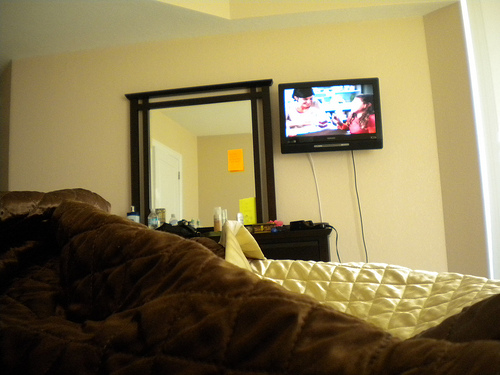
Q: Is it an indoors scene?
A: Yes, it is indoors.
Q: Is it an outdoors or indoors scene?
A: It is indoors.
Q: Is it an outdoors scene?
A: No, it is indoors.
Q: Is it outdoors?
A: No, it is indoors.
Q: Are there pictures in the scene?
A: No, there are no pictures.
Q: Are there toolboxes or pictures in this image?
A: No, there are no pictures or toolboxes.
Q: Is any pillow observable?
A: No, there are no pillows.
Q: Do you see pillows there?
A: No, there are no pillows.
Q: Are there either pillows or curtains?
A: No, there are no pillows or curtains.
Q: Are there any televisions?
A: Yes, there is a television.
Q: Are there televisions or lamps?
A: Yes, there is a television.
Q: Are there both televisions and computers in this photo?
A: No, there is a television but no computers.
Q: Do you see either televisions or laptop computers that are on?
A: Yes, the television is on.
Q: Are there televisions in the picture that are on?
A: Yes, there is a television that is on.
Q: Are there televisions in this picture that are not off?
A: Yes, there is a television that is on.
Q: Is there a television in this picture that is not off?
A: Yes, there is a television that is on.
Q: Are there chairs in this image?
A: No, there are no chairs.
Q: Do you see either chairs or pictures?
A: No, there are no chairs or pictures.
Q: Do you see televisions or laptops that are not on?
A: No, there is a television but it is on.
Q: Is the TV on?
A: Yes, the TV is on.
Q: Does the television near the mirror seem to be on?
A: Yes, the TV is on.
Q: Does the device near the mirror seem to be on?
A: Yes, the TV is on.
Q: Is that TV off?
A: No, the TV is on.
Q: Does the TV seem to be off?
A: No, the TV is on.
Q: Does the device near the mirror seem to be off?
A: No, the TV is on.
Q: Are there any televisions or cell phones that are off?
A: No, there is a television but it is on.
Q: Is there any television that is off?
A: No, there is a television but it is on.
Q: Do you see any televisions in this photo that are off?
A: No, there is a television but it is on.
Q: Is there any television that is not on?
A: No, there is a television but it is on.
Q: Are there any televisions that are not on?
A: No, there is a television but it is on.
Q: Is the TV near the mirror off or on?
A: The television is on.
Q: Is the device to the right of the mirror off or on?
A: The television is on.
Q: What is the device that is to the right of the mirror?
A: The device is a television.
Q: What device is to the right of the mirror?
A: The device is a television.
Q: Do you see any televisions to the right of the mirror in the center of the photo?
A: Yes, there is a television to the right of the mirror.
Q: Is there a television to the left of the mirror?
A: No, the television is to the right of the mirror.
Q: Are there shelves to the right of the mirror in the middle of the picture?
A: No, there is a television to the right of the mirror.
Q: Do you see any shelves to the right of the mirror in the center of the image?
A: No, there is a television to the right of the mirror.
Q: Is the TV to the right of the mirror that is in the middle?
A: Yes, the TV is to the right of the mirror.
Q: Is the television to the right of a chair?
A: No, the television is to the right of the mirror.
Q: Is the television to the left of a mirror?
A: No, the television is to the right of a mirror.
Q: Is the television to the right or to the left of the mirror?
A: The television is to the right of the mirror.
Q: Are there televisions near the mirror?
A: Yes, there is a television near the mirror.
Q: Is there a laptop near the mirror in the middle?
A: No, there is a television near the mirror.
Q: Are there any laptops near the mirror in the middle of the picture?
A: No, there is a television near the mirror.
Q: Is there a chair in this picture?
A: No, there are no chairs.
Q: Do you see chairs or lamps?
A: No, there are no chairs or lamps.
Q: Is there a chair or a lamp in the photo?
A: No, there are no chairs or lamps.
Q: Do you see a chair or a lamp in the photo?
A: No, there are no chairs or lamps.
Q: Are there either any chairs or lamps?
A: No, there are no chairs or lamps.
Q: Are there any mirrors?
A: Yes, there is a mirror.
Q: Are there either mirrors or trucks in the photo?
A: Yes, there is a mirror.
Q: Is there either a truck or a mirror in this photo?
A: Yes, there is a mirror.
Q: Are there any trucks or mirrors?
A: Yes, there is a mirror.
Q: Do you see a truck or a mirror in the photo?
A: Yes, there is a mirror.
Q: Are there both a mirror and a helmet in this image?
A: No, there is a mirror but no helmets.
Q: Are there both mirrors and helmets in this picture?
A: No, there is a mirror but no helmets.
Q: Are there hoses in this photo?
A: No, there are no hoses.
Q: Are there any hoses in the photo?
A: No, there are no hoses.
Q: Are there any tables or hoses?
A: No, there are no hoses or tables.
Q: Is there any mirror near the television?
A: Yes, there is a mirror near the television.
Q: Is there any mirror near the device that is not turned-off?
A: Yes, there is a mirror near the television.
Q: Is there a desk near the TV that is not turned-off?
A: No, there is a mirror near the television.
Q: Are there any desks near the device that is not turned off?
A: No, there is a mirror near the television.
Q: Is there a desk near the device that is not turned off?
A: No, there is a mirror near the television.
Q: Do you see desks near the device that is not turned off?
A: No, there is a mirror near the television.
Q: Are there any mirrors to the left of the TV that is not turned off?
A: Yes, there is a mirror to the left of the TV.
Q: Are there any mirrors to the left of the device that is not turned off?
A: Yes, there is a mirror to the left of the TV.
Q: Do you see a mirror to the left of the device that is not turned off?
A: Yes, there is a mirror to the left of the TV.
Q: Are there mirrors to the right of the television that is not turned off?
A: No, the mirror is to the left of the TV.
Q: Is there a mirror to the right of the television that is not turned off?
A: No, the mirror is to the left of the TV.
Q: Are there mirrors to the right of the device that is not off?
A: No, the mirror is to the left of the TV.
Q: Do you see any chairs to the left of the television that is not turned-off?
A: No, there is a mirror to the left of the TV.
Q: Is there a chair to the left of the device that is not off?
A: No, there is a mirror to the left of the TV.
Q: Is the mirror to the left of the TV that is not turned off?
A: Yes, the mirror is to the left of the TV.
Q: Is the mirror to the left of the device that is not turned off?
A: Yes, the mirror is to the left of the TV.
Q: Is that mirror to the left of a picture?
A: No, the mirror is to the left of the TV.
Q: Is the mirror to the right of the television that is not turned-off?
A: No, the mirror is to the left of the TV.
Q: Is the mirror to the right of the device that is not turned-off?
A: No, the mirror is to the left of the TV.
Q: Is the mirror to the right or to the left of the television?
A: The mirror is to the left of the television.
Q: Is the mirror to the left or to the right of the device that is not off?
A: The mirror is to the left of the television.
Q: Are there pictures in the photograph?
A: No, there are no pictures.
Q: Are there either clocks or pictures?
A: No, there are no pictures or clocks.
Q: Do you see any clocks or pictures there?
A: No, there are no pictures or clocks.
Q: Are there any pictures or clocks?
A: No, there are no pictures or clocks.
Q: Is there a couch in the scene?
A: No, there are no couches.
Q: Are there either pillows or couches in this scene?
A: No, there are no couches or pillows.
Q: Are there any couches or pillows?
A: No, there are no couches or pillows.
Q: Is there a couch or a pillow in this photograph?
A: No, there are no couches or pillows.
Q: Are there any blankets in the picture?
A: Yes, there is a blanket.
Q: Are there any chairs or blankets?
A: Yes, there is a blanket.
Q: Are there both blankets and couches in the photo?
A: No, there is a blanket but no couches.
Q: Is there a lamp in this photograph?
A: No, there are no lamps.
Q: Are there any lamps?
A: No, there are no lamps.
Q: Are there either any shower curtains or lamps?
A: No, there are no lamps or shower curtains.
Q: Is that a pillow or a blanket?
A: That is a blanket.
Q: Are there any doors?
A: Yes, there is a door.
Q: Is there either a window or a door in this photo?
A: Yes, there is a door.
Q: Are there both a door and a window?
A: No, there is a door but no windows.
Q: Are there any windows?
A: No, there are no windows.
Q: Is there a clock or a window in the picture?
A: No, there are no windows or clocks.